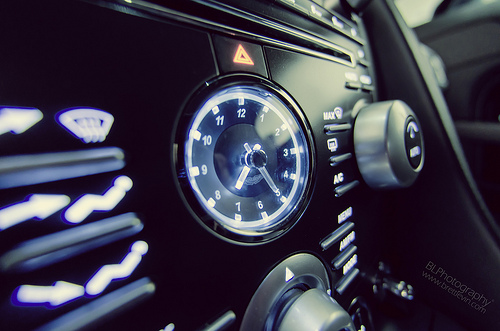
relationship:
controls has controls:
[348, 93, 428, 194] [248, 255, 350, 330]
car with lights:
[0, 0, 499, 331] [1, 8, 453, 326]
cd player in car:
[146, 0, 330, 100] [0, 0, 499, 331]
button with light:
[208, 32, 273, 82] [232, 43, 254, 64]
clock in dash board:
[185, 85, 309, 232] [2, 0, 499, 330]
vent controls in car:
[0, 106, 150, 327] [4, 5, 493, 330]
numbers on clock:
[184, 99, 307, 228] [163, 71, 333, 256]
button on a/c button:
[22, 44, 453, 324] [4, 105, 165, 330]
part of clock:
[235, 144, 283, 221] [209, 81, 312, 208]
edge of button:
[381, 117, 401, 182] [345, 90, 429, 202]